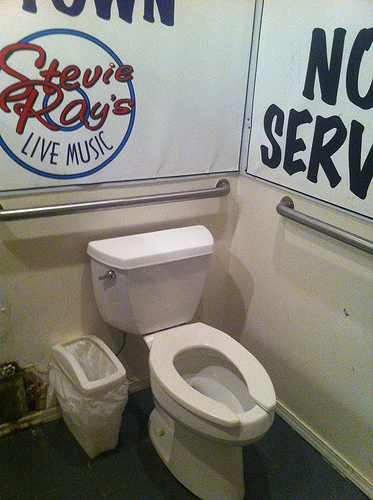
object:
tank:
[85, 225, 214, 337]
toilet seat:
[148, 322, 278, 429]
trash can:
[47, 333, 129, 460]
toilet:
[86, 223, 276, 500]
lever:
[97, 270, 116, 281]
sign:
[0, 0, 256, 191]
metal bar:
[0, 177, 231, 224]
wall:
[1, 0, 257, 385]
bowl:
[142, 319, 277, 500]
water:
[181, 375, 245, 416]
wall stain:
[0, 359, 29, 422]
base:
[148, 403, 247, 500]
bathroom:
[0, 0, 373, 500]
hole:
[20, 363, 50, 412]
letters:
[258, 23, 373, 199]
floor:
[0, 384, 372, 500]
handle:
[98, 269, 116, 281]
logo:
[0, 28, 137, 180]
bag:
[45, 338, 129, 430]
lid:
[50, 332, 128, 395]